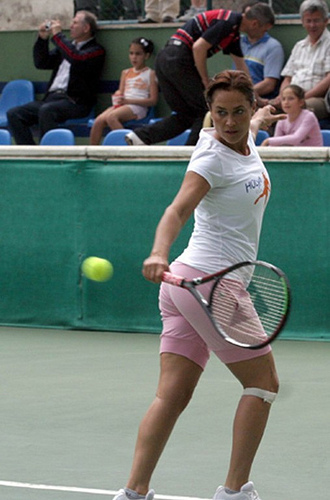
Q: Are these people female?
A: No, they are both male and female.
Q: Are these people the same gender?
A: No, they are both male and female.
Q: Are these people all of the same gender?
A: No, they are both male and female.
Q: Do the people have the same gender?
A: No, they are both male and female.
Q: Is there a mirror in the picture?
A: No, there are no mirrors.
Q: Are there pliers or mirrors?
A: No, there are no mirrors or pliers.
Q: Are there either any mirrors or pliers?
A: No, there are no mirrors or pliers.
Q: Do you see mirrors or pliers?
A: No, there are no mirrors or pliers.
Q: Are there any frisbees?
A: No, there are no frisbees.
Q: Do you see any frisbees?
A: No, there are no frisbees.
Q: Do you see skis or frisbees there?
A: No, there are no frisbees or skis.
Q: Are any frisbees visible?
A: No, there are no frisbees.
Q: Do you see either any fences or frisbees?
A: No, there are no frisbees or fences.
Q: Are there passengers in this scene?
A: No, there are no passengers.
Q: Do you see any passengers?
A: No, there are no passengers.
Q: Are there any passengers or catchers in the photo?
A: No, there are no passengers or catchers.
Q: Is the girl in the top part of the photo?
A: Yes, the girl is in the top of the image.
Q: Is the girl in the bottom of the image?
A: No, the girl is in the top of the image.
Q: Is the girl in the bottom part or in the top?
A: The girl is in the top of the image.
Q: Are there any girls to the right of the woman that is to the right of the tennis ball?
A: Yes, there is a girl to the right of the woman.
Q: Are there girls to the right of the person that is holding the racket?
A: Yes, there is a girl to the right of the woman.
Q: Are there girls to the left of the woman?
A: No, the girl is to the right of the woman.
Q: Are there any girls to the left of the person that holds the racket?
A: No, the girl is to the right of the woman.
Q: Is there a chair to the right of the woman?
A: No, there is a girl to the right of the woman.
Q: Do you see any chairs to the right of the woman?
A: No, there is a girl to the right of the woman.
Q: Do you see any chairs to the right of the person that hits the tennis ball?
A: No, there is a girl to the right of the woman.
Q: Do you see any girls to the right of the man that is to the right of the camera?
A: Yes, there is a girl to the right of the man.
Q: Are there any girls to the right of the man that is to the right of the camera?
A: Yes, there is a girl to the right of the man.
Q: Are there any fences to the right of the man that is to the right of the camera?
A: No, there is a girl to the right of the man.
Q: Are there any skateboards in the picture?
A: No, there are no skateboards.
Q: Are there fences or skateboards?
A: No, there are no skateboards or fences.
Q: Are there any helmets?
A: No, there are no helmets.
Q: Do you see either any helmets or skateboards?
A: No, there are no helmets or skateboards.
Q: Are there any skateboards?
A: No, there are no skateboards.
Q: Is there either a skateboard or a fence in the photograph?
A: No, there are no skateboards or fences.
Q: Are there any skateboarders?
A: No, there are no skateboarders.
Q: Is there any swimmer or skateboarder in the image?
A: No, there are no skateboarders or swimmers.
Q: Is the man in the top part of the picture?
A: Yes, the man is in the top of the image.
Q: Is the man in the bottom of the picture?
A: No, the man is in the top of the image.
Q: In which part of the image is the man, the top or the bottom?
A: The man is in the top of the image.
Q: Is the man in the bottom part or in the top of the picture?
A: The man is in the top of the image.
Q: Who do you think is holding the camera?
A: The man is holding the camera.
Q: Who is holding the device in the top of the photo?
A: The man is holding the camera.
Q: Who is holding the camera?
A: The man is holding the camera.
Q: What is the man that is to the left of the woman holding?
A: The man is holding the camera.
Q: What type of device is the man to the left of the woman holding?
A: The man is holding the camera.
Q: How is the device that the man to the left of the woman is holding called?
A: The device is a camera.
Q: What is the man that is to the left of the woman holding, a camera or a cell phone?
A: The man is holding a camera.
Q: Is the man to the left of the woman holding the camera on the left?
A: Yes, the man is holding the camera.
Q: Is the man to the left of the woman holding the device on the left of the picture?
A: Yes, the man is holding the camera.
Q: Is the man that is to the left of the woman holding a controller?
A: No, the man is holding the camera.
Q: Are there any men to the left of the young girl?
A: Yes, there is a man to the left of the girl.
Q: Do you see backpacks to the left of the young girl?
A: No, there is a man to the left of the girl.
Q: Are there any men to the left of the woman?
A: Yes, there is a man to the left of the woman.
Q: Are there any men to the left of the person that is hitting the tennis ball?
A: Yes, there is a man to the left of the woman.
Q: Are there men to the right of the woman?
A: No, the man is to the left of the woman.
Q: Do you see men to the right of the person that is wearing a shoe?
A: No, the man is to the left of the woman.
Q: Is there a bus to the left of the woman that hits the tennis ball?
A: No, there is a man to the left of the woman.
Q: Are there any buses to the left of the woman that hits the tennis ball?
A: No, there is a man to the left of the woman.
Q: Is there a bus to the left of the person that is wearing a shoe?
A: No, there is a man to the left of the woman.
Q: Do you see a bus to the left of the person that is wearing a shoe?
A: No, there is a man to the left of the woman.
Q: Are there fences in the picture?
A: No, there are no fences.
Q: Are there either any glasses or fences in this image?
A: No, there are no fences or glasses.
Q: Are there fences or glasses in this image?
A: No, there are no fences or glasses.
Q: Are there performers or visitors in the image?
A: No, there are no visitors or performers.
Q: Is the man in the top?
A: Yes, the man is in the top of the image.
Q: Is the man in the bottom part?
A: No, the man is in the top of the image.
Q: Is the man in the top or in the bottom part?
A: The man is in the top of the image.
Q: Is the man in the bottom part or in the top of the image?
A: The man is in the top of the image.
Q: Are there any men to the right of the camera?
A: Yes, there is a man to the right of the camera.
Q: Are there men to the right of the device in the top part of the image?
A: Yes, there is a man to the right of the camera.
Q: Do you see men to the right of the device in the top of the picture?
A: Yes, there is a man to the right of the camera.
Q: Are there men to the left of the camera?
A: No, the man is to the right of the camera.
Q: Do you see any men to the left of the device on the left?
A: No, the man is to the right of the camera.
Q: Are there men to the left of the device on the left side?
A: No, the man is to the right of the camera.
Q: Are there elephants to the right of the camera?
A: No, there is a man to the right of the camera.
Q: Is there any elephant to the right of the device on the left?
A: No, there is a man to the right of the camera.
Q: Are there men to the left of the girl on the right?
A: Yes, there is a man to the left of the girl.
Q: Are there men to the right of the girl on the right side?
A: No, the man is to the left of the girl.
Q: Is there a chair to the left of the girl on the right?
A: No, there is a man to the left of the girl.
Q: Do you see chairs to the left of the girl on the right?
A: No, there is a man to the left of the girl.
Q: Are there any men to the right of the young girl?
A: Yes, there is a man to the right of the girl.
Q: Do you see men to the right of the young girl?
A: Yes, there is a man to the right of the girl.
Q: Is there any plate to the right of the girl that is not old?
A: No, there is a man to the right of the girl.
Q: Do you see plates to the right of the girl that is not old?
A: No, there is a man to the right of the girl.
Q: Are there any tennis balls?
A: Yes, there is a tennis ball.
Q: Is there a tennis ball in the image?
A: Yes, there is a tennis ball.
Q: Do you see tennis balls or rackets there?
A: Yes, there is a tennis ball.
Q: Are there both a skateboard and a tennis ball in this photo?
A: No, there is a tennis ball but no skateboards.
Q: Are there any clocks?
A: No, there are no clocks.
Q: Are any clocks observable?
A: No, there are no clocks.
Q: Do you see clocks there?
A: No, there are no clocks.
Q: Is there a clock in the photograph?
A: No, there are no clocks.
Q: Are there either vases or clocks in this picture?
A: No, there are no clocks or vases.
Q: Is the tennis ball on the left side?
A: Yes, the tennis ball is on the left of the image.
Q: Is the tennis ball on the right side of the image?
A: No, the tennis ball is on the left of the image.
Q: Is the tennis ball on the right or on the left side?
A: The tennis ball is on the left of the image.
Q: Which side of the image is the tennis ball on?
A: The tennis ball is on the left of the image.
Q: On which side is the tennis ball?
A: The tennis ball is on the left of the image.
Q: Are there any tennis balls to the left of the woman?
A: Yes, there is a tennis ball to the left of the woman.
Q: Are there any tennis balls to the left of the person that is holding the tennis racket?
A: Yes, there is a tennis ball to the left of the woman.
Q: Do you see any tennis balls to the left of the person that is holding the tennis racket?
A: Yes, there is a tennis ball to the left of the woman.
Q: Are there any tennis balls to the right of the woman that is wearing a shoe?
A: No, the tennis ball is to the left of the woman.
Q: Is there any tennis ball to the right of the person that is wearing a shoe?
A: No, the tennis ball is to the left of the woman.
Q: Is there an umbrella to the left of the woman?
A: No, there is a tennis ball to the left of the woman.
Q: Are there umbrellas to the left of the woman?
A: No, there is a tennis ball to the left of the woman.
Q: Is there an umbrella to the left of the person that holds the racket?
A: No, there is a tennis ball to the left of the woman.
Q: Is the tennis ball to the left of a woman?
A: Yes, the tennis ball is to the left of a woman.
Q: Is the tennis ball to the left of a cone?
A: No, the tennis ball is to the left of a woman.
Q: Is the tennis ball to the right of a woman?
A: No, the tennis ball is to the left of a woman.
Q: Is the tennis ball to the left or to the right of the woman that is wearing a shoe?
A: The tennis ball is to the left of the woman.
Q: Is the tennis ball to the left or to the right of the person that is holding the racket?
A: The tennis ball is to the left of the woman.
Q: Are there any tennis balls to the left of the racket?
A: Yes, there is a tennis ball to the left of the racket.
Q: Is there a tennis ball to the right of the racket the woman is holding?
A: No, the tennis ball is to the left of the tennis racket.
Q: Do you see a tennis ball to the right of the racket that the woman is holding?
A: No, the tennis ball is to the left of the tennis racket.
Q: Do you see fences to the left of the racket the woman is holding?
A: No, there is a tennis ball to the left of the racket.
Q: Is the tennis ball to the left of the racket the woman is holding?
A: Yes, the tennis ball is to the left of the tennis racket.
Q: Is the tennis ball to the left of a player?
A: No, the tennis ball is to the left of the tennis racket.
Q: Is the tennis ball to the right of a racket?
A: No, the tennis ball is to the left of a racket.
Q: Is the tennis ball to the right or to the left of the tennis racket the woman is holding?
A: The tennis ball is to the left of the tennis racket.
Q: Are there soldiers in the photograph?
A: No, there are no soldiers.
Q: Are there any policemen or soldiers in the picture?
A: No, there are no soldiers or policemen.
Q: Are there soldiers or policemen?
A: No, there are no soldiers or policemen.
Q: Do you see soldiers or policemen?
A: No, there are no soldiers or policemen.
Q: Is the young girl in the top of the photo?
A: Yes, the girl is in the top of the image.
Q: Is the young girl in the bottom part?
A: No, the girl is in the top of the image.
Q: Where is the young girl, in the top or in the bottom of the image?
A: The girl is in the top of the image.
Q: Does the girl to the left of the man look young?
A: Yes, the girl is young.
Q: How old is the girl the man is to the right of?
A: The girl is young.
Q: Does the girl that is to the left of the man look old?
A: No, the girl is young.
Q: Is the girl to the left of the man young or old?
A: The girl is young.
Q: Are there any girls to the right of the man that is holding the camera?
A: Yes, there is a girl to the right of the man.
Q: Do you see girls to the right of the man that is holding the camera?
A: Yes, there is a girl to the right of the man.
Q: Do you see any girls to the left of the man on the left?
A: No, the girl is to the right of the man.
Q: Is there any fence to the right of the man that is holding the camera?
A: No, there is a girl to the right of the man.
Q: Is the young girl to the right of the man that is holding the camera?
A: Yes, the girl is to the right of the man.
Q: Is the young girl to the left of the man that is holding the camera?
A: No, the girl is to the right of the man.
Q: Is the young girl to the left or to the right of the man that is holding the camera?
A: The girl is to the right of the man.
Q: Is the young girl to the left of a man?
A: Yes, the girl is to the left of a man.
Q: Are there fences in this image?
A: No, there are no fences.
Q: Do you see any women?
A: Yes, there is a woman.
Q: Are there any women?
A: Yes, there is a woman.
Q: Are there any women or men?
A: Yes, there is a woman.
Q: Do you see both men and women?
A: Yes, there are both a woman and a man.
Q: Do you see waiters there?
A: No, there are no waiters.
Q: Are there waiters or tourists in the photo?
A: No, there are no waiters or tourists.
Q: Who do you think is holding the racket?
A: The woman is holding the racket.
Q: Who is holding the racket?
A: The woman is holding the racket.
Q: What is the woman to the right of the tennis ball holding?
A: The woman is holding the racket.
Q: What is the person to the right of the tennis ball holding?
A: The woman is holding the racket.